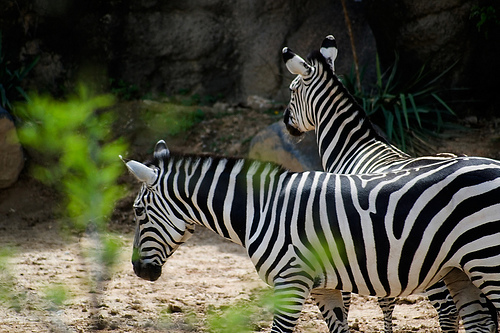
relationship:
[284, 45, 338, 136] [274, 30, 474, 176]
head on zebra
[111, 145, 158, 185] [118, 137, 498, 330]
ear on zebra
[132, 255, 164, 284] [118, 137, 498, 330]
mouth on zebra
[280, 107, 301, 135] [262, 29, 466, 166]
mouth on zebra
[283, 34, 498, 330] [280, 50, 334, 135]
zebra has head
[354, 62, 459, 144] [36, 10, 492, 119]
plant between rocks